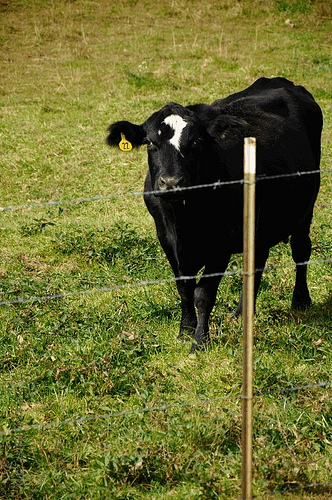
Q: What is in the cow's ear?
A: Number tag.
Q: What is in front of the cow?
A: Barbwire.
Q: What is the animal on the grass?
A: A cow.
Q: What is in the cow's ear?
A: A yellow tag.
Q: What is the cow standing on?
A: Grass.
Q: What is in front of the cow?
A: A fence.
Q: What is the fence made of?
A: Barbed wire.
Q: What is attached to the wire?
A: Wooden rod.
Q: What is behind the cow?
A: Grass field.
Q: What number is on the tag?
A: 22.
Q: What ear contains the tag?
A: Right ear.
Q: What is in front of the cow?
A: Barbed wire fence.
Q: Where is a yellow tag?
A: On cow's ear.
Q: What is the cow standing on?
A: Grass.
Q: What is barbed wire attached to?
A: Brown pole.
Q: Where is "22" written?
A: On yellow tag.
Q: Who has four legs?
A: The cow.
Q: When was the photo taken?
A: During the daytime.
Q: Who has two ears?
A: The cow.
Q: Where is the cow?
A: On grassy field.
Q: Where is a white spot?
A: On cow's head.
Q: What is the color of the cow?
A: Black.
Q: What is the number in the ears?
A: 22.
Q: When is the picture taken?
A: Daytime.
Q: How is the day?
A: Sunny.